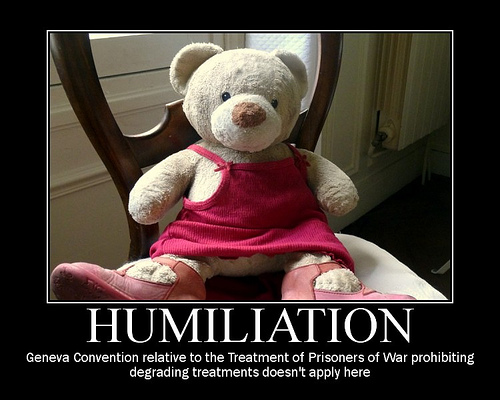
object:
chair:
[49, 29, 451, 302]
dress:
[149, 146, 357, 274]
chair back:
[50, 32, 345, 262]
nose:
[229, 104, 268, 130]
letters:
[84, 306, 123, 345]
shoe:
[277, 263, 419, 301]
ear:
[165, 43, 223, 98]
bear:
[47, 39, 416, 304]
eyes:
[269, 97, 280, 106]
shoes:
[50, 252, 208, 300]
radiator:
[370, 30, 452, 153]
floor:
[339, 173, 452, 300]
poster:
[12, 8, 483, 400]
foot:
[280, 265, 419, 301]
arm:
[127, 146, 196, 225]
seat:
[336, 231, 451, 301]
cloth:
[247, 173, 291, 211]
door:
[48, 33, 249, 194]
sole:
[49, 265, 133, 301]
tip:
[406, 294, 416, 303]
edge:
[437, 292, 450, 303]